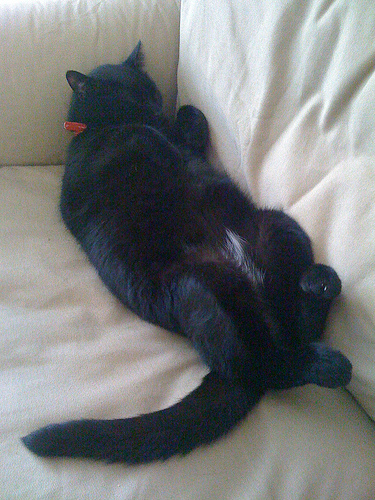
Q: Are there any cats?
A: Yes, there is a cat.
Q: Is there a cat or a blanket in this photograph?
A: Yes, there is a cat.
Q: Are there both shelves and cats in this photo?
A: No, there is a cat but no shelves.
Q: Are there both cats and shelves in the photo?
A: No, there is a cat but no shelves.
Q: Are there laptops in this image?
A: No, there are no laptops.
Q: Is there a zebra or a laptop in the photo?
A: No, there are no laptops or zebras.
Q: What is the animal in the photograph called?
A: The animal is a cat.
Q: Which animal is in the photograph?
A: The animal is a cat.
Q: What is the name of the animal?
A: The animal is a cat.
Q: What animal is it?
A: The animal is a cat.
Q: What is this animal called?
A: This is a cat.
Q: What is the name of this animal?
A: This is a cat.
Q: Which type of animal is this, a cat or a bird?
A: This is a cat.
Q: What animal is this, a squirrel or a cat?
A: This is a cat.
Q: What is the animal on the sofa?
A: The animal is a cat.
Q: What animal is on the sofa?
A: The animal is a cat.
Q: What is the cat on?
A: The cat is on the sofa.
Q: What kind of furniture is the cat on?
A: The cat is on the sofa.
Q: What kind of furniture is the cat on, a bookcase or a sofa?
A: The cat is on a sofa.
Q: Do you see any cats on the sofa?
A: Yes, there is a cat on the sofa.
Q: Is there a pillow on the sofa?
A: No, there is a cat on the sofa.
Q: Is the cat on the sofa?
A: Yes, the cat is on the sofa.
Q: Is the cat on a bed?
A: No, the cat is on the sofa.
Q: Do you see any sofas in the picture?
A: Yes, there is a sofa.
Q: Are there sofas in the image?
A: Yes, there is a sofa.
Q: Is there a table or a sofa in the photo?
A: Yes, there is a sofa.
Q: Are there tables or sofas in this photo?
A: Yes, there is a sofa.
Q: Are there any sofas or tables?
A: Yes, there is a sofa.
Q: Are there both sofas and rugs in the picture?
A: No, there is a sofa but no rugs.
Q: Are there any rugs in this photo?
A: No, there are no rugs.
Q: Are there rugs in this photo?
A: No, there are no rugs.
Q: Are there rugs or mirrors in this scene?
A: No, there are no rugs or mirrors.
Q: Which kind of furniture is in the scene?
A: The furniture is a sofa.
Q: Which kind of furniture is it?
A: The piece of furniture is a sofa.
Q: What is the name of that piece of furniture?
A: That is a sofa.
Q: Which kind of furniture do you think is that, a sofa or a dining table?
A: That is a sofa.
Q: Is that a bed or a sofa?
A: That is a sofa.